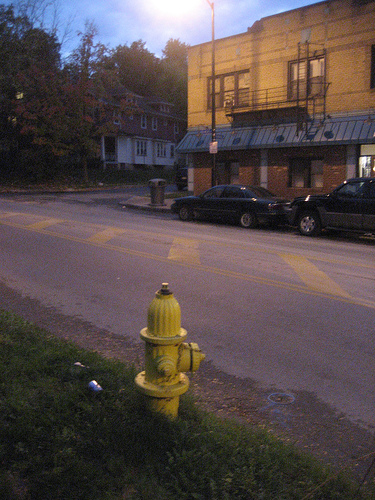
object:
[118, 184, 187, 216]
sidewalk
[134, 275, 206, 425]
hydrant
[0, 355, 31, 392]
leaves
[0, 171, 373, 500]
ground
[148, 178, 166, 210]
can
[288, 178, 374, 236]
car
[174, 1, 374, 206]
building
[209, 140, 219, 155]
sign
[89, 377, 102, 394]
can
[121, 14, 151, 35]
sky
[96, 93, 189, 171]
house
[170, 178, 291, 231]
car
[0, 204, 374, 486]
road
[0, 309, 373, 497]
grass